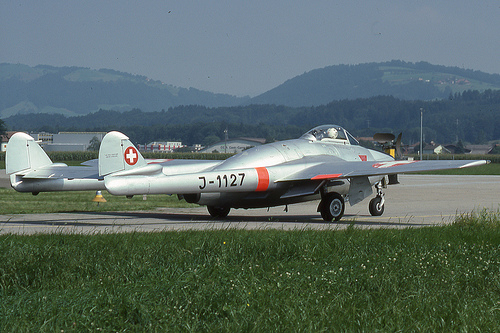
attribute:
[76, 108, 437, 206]
plane — silver, parked, grey, gray, black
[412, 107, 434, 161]
pole — tall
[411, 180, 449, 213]
runway — green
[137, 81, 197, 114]
mountains — far, green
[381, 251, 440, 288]
grass — green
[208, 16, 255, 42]
sky — blue